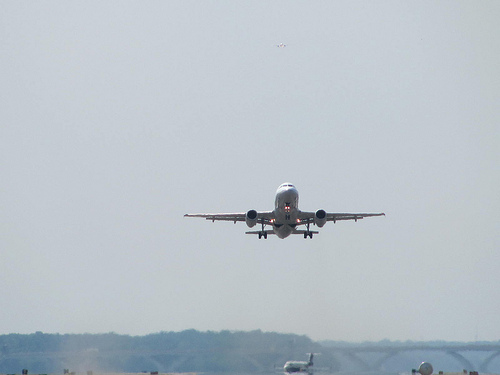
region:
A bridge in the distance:
[330, 347, 499, 374]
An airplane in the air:
[185, 180, 387, 240]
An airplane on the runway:
[277, 353, 325, 373]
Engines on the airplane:
[245, 209, 328, 224]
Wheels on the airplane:
[283, 211, 293, 221]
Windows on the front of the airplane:
[280, 183, 294, 186]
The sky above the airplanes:
[0, 2, 498, 337]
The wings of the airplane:
[183, 211, 383, 223]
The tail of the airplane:
[302, 350, 320, 362]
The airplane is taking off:
[183, 181, 386, 238]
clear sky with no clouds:
[1, 3, 498, 172]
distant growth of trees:
[2, 333, 329, 373]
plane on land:
[278, 349, 327, 374]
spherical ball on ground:
[416, 358, 435, 373]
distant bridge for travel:
[6, 345, 498, 374]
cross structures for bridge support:
[343, 351, 400, 373]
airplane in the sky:
[181, 183, 387, 238]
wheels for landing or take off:
[253, 226, 315, 241]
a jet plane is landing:
[185, 181, 411, 279]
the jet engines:
[245, 202, 332, 233]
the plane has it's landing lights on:
[255, 200, 305, 225]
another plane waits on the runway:
[276, 350, 330, 374]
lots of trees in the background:
[32, 325, 269, 367]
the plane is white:
[180, 167, 380, 239]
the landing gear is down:
[241, 211, 313, 246]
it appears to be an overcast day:
[130, 135, 462, 330]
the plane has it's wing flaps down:
[153, 163, 396, 245]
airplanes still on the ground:
[101, 354, 459, 374]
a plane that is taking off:
[183, 189, 385, 244]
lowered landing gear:
[250, 219, 321, 241]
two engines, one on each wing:
[244, 205, 327, 228]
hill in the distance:
[6, 323, 331, 372]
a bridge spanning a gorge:
[321, 341, 498, 365]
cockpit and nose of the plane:
[278, 177, 305, 200]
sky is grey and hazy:
[1, 24, 498, 374]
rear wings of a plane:
[244, 222, 318, 242]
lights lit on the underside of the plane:
[271, 199, 304, 229]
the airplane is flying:
[140, 153, 432, 291]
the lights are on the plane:
[262, 194, 313, 245]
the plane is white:
[157, 166, 389, 266]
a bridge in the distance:
[320, 326, 487, 368]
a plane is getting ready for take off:
[265, 330, 335, 370]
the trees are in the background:
[55, 312, 320, 369]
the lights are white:
[252, 195, 310, 234]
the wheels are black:
[294, 224, 323, 255]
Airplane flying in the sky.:
[175, 174, 410, 247]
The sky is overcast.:
[41, 36, 482, 219]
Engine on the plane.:
[242, 208, 257, 230]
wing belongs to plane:
[301, 209, 385, 228]